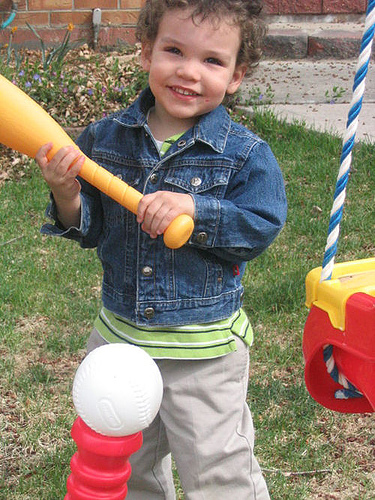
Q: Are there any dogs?
A: No, there are no dogs.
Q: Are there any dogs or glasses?
A: No, there are no dogs or glasses.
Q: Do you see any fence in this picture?
A: No, there are no fences.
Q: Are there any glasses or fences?
A: No, there are no fences or glasses.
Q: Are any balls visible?
A: Yes, there is a ball.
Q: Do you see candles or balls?
A: Yes, there is a ball.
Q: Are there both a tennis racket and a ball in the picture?
A: No, there is a ball but no rackets.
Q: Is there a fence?
A: No, there are no fences.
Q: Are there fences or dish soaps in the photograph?
A: No, there are no fences or dish soaps.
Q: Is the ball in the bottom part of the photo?
A: Yes, the ball is in the bottom of the image.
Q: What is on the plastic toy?
A: The ball is on the toy.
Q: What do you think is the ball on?
A: The ball is on the toy.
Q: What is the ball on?
A: The ball is on the toy.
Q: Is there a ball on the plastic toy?
A: Yes, there is a ball on the toy.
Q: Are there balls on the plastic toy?
A: Yes, there is a ball on the toy.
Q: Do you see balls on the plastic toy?
A: Yes, there is a ball on the toy.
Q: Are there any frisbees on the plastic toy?
A: No, there is a ball on the toy.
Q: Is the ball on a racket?
A: No, the ball is on a toy.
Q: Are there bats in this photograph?
A: Yes, there is a bat.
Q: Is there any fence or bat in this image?
A: Yes, there is a bat.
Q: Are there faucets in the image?
A: No, there are no faucets.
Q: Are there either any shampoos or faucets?
A: No, there are no faucets or shampoos.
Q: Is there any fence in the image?
A: No, there are no fences.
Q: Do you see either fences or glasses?
A: No, there are no fences or glasses.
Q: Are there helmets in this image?
A: No, there are no helmets.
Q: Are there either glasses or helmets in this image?
A: No, there are no helmets or glasses.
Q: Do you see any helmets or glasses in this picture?
A: No, there are no helmets or glasses.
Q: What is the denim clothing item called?
A: The clothing item is a jacket.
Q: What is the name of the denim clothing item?
A: The clothing item is a jacket.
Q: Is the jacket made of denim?
A: Yes, the jacket is made of denim.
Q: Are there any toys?
A: Yes, there is a toy.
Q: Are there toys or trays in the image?
A: Yes, there is a toy.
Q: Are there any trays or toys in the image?
A: Yes, there is a toy.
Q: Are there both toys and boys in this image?
A: Yes, there are both a toy and a boy.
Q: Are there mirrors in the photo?
A: No, there are no mirrors.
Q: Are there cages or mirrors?
A: No, there are no mirrors or cages.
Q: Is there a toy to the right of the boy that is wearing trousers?
A: Yes, there is a toy to the right of the boy.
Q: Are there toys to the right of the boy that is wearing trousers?
A: Yes, there is a toy to the right of the boy.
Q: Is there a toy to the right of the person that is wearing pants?
A: Yes, there is a toy to the right of the boy.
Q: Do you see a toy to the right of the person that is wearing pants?
A: Yes, there is a toy to the right of the boy.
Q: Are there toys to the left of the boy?
A: No, the toy is to the right of the boy.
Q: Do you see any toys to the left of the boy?
A: No, the toy is to the right of the boy.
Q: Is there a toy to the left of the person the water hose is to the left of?
A: No, the toy is to the right of the boy.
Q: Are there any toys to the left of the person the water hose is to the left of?
A: No, the toy is to the right of the boy.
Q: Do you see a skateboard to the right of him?
A: No, there is a toy to the right of the boy.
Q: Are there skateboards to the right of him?
A: No, there is a toy to the right of the boy.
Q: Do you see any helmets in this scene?
A: No, there are no helmets.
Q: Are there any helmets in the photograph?
A: No, there are no helmets.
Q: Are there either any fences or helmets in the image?
A: No, there are no helmets or fences.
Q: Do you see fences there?
A: No, there are no fences.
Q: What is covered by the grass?
A: The ground is covered by the grass.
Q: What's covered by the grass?
A: The ground is covered by the grass.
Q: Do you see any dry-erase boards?
A: No, there are no dry-erase boards.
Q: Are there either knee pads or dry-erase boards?
A: No, there are no dry-erase boards or knee pads.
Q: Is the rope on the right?
A: Yes, the rope is on the right of the image.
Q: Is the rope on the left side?
A: No, the rope is on the right of the image.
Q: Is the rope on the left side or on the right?
A: The rope is on the right of the image.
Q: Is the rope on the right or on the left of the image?
A: The rope is on the right of the image.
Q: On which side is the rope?
A: The rope is on the right of the image.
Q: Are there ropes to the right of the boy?
A: Yes, there is a rope to the right of the boy.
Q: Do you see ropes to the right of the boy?
A: Yes, there is a rope to the right of the boy.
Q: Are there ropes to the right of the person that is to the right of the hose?
A: Yes, there is a rope to the right of the boy.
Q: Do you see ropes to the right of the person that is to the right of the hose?
A: Yes, there is a rope to the right of the boy.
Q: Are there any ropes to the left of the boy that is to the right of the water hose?
A: No, the rope is to the right of the boy.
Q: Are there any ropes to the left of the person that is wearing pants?
A: No, the rope is to the right of the boy.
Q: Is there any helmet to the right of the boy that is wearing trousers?
A: No, there is a rope to the right of the boy.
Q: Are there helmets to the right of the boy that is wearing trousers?
A: No, there is a rope to the right of the boy.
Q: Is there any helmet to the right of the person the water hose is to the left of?
A: No, there is a rope to the right of the boy.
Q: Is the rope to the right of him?
A: Yes, the rope is to the right of the boy.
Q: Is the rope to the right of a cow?
A: No, the rope is to the right of the boy.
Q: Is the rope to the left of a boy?
A: No, the rope is to the right of a boy.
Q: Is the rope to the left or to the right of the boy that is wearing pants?
A: The rope is to the right of the boy.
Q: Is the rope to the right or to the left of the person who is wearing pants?
A: The rope is to the right of the boy.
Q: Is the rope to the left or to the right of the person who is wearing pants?
A: The rope is to the right of the boy.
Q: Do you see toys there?
A: Yes, there is a toy.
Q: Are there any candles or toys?
A: Yes, there is a toy.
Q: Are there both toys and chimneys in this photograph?
A: No, there is a toy but no chimneys.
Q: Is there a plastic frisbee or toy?
A: Yes, there is a plastic toy.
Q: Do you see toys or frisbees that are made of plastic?
A: Yes, the toy is made of plastic.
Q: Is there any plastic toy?
A: Yes, there is a toy that is made of plastic.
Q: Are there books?
A: No, there are no books.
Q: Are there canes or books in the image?
A: No, there are no books or canes.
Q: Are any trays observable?
A: No, there are no trays.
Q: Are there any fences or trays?
A: No, there are no trays or fences.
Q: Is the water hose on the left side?
A: Yes, the water hose is on the left of the image.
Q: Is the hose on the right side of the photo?
A: No, the hose is on the left of the image.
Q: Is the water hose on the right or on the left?
A: The water hose is on the left of the image.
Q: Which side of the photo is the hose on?
A: The hose is on the left of the image.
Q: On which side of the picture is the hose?
A: The hose is on the left of the image.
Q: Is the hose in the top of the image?
A: Yes, the hose is in the top of the image.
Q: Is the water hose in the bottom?
A: No, the water hose is in the top of the image.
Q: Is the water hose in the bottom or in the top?
A: The water hose is in the top of the image.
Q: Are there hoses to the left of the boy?
A: Yes, there is a hose to the left of the boy.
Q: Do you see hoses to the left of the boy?
A: Yes, there is a hose to the left of the boy.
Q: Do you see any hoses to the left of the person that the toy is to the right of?
A: Yes, there is a hose to the left of the boy.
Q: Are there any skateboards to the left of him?
A: No, there is a hose to the left of the boy.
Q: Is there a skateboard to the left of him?
A: No, there is a hose to the left of the boy.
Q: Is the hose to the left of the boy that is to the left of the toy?
A: Yes, the hose is to the left of the boy.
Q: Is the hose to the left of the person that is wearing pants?
A: Yes, the hose is to the left of the boy.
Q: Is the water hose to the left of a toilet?
A: No, the water hose is to the left of the boy.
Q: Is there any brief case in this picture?
A: No, there are no briefcases.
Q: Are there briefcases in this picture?
A: No, there are no briefcases.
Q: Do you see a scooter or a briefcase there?
A: No, there are no briefcases or scooters.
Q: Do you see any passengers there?
A: No, there are no passengers.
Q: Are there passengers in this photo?
A: No, there are no passengers.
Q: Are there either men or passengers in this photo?
A: No, there are no passengers or men.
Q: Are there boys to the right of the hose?
A: Yes, there is a boy to the right of the hose.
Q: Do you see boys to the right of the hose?
A: Yes, there is a boy to the right of the hose.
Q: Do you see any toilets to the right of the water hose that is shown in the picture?
A: No, there is a boy to the right of the water hose.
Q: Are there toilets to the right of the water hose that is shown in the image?
A: No, there is a boy to the right of the water hose.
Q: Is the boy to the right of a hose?
A: Yes, the boy is to the right of a hose.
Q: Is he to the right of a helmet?
A: No, the boy is to the right of a hose.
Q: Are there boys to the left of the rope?
A: Yes, there is a boy to the left of the rope.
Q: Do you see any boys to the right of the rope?
A: No, the boy is to the left of the rope.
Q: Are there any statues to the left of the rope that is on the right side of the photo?
A: No, there is a boy to the left of the rope.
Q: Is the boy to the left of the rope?
A: Yes, the boy is to the left of the rope.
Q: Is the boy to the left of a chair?
A: No, the boy is to the left of the rope.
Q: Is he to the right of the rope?
A: No, the boy is to the left of the rope.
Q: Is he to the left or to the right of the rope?
A: The boy is to the left of the rope.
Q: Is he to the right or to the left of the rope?
A: The boy is to the left of the rope.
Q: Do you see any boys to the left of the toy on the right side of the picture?
A: Yes, there is a boy to the left of the toy.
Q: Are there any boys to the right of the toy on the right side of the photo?
A: No, the boy is to the left of the toy.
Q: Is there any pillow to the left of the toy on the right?
A: No, there is a boy to the left of the toy.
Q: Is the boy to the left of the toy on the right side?
A: Yes, the boy is to the left of the toy.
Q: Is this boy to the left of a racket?
A: No, the boy is to the left of the toy.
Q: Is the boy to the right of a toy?
A: No, the boy is to the left of a toy.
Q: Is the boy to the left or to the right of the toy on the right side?
A: The boy is to the left of the toy.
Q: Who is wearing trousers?
A: The boy is wearing trousers.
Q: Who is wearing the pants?
A: The boy is wearing trousers.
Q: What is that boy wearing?
A: The boy is wearing trousers.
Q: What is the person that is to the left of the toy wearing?
A: The boy is wearing trousers.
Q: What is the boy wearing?
A: The boy is wearing trousers.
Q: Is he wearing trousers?
A: Yes, the boy is wearing trousers.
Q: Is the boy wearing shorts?
A: No, the boy is wearing trousers.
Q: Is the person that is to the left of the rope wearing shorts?
A: No, the boy is wearing trousers.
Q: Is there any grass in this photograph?
A: Yes, there is grass.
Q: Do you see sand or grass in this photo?
A: Yes, there is grass.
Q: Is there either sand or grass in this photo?
A: Yes, there is grass.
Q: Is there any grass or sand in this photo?
A: Yes, there is grass.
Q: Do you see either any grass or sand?
A: Yes, there is grass.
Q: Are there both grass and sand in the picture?
A: No, there is grass but no sand.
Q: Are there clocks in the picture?
A: No, there are no clocks.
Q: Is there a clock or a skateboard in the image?
A: No, there are no clocks or skateboards.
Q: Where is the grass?
A: The grass is on the ground.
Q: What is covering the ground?
A: The grass is covering the ground.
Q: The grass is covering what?
A: The grass is covering the ground.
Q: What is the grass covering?
A: The grass is covering the ground.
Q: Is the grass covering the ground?
A: Yes, the grass is covering the ground.